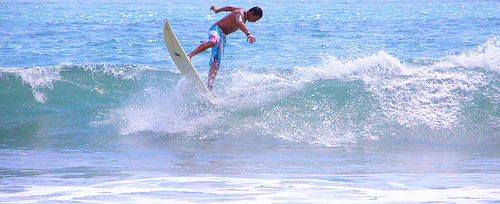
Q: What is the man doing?
A: Surfing.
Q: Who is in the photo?
A: A surfer.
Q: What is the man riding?
A: A surfboard.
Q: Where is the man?
A: In the ocean.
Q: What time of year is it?
A: Summer.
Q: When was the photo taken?
A: Daytime.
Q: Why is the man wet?
A: He's surfing.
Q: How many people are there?
A: One.